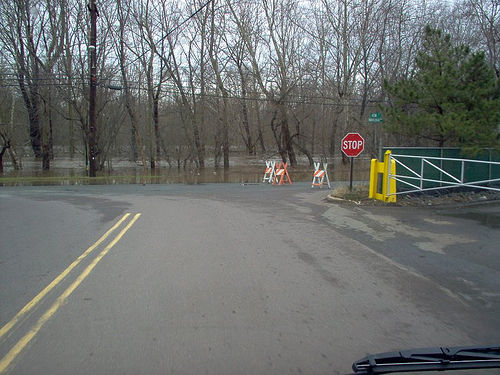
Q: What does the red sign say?
A: Stop.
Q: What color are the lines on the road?
A: Yellow.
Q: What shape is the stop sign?
A: An octogon.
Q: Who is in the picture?
A: No one is in the picture.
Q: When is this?
A: Daytime.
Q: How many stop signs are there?
A: One.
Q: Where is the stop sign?
A: On the street corner.